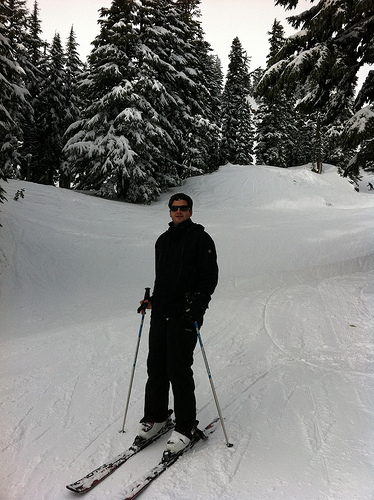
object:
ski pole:
[189, 316, 232, 446]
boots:
[163, 421, 200, 459]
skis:
[121, 388, 224, 500]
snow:
[0, 174, 374, 489]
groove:
[263, 316, 282, 351]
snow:
[78, 142, 101, 154]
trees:
[62, 0, 181, 198]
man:
[119, 181, 228, 459]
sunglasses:
[166, 204, 192, 211]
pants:
[142, 311, 199, 434]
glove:
[193, 308, 213, 327]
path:
[7, 168, 109, 235]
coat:
[148, 216, 225, 307]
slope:
[229, 188, 362, 473]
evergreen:
[217, 31, 260, 171]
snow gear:
[161, 231, 187, 395]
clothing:
[140, 218, 219, 433]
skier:
[69, 192, 233, 500]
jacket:
[149, 218, 219, 319]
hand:
[182, 310, 203, 334]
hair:
[168, 192, 193, 207]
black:
[149, 218, 219, 325]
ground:
[0, 162, 374, 500]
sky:
[24, 0, 357, 88]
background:
[0, 0, 373, 202]